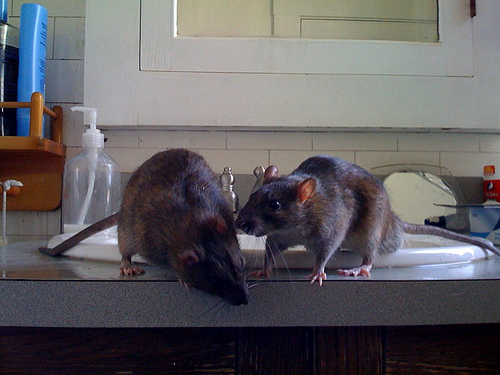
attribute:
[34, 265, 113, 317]
counter — grey, laminated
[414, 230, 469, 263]
sink — white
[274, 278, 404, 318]
ledge — gray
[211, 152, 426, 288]
mouse — grey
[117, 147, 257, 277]
mouse — grey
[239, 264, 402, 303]
paws — pink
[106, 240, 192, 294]
paws — pink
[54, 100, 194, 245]
bottle — plastic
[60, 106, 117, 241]
bottle — clear, transparent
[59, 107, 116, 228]
bottle — clear, squirt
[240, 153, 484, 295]
mouse — grey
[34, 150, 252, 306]
rodent — large, rat-type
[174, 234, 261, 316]
head — large, rat-type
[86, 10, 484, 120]
chest — medicine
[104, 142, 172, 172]
tile — white, ceramic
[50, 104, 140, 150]
tile — ceramic, white